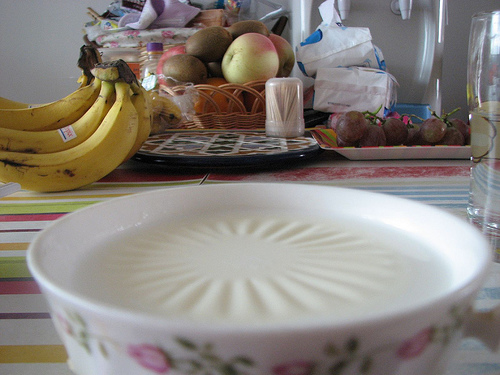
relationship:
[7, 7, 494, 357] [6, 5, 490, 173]
area in kitchen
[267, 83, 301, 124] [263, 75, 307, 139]
toothpicks in container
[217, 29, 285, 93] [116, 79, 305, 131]
apple in basket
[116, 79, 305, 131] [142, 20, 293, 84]
basket of fruits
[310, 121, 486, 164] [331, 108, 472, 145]
plate with fruits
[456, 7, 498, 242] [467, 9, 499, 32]
glass for drinking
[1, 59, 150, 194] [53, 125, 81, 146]
bananas has sticker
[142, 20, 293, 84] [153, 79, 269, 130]
fruits in basket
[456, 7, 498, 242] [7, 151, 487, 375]
glass on table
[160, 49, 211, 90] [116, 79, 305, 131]
kiwi in basket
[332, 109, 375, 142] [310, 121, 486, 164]
grape on plate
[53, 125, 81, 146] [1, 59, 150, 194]
sticker on bananas